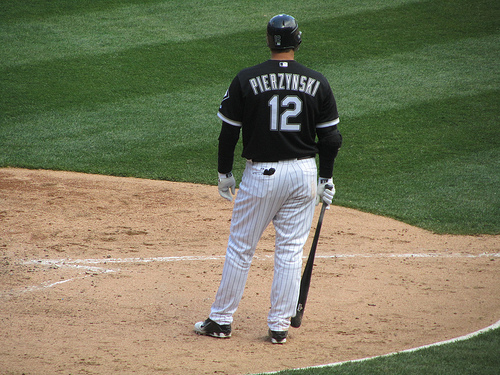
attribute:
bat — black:
[295, 174, 338, 344]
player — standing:
[195, 14, 332, 349]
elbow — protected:
[319, 130, 351, 152]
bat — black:
[293, 181, 330, 337]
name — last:
[243, 72, 322, 94]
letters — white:
[248, 71, 323, 102]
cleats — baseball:
[194, 318, 289, 345]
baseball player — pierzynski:
[213, 13, 333, 343]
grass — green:
[1, 0, 497, 374]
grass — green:
[334, 12, 494, 207]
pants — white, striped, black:
[195, 158, 335, 362]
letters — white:
[245, 67, 329, 97]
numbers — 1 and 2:
[269, 94, 301, 131]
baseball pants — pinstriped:
[233, 159, 316, 239]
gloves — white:
[316, 180, 338, 205]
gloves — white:
[215, 177, 232, 200]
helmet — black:
[265, 12, 302, 54]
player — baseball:
[206, 9, 366, 327]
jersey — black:
[222, 70, 341, 158]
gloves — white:
[210, 174, 337, 207]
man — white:
[210, 5, 340, 355]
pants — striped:
[217, 143, 311, 337]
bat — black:
[286, 188, 349, 358]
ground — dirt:
[21, 181, 157, 336]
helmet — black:
[236, 15, 345, 58]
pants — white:
[223, 158, 318, 326]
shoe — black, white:
[191, 315, 235, 337]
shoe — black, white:
[265, 322, 291, 345]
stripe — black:
[263, 182, 269, 216]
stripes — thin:
[209, 157, 319, 328]